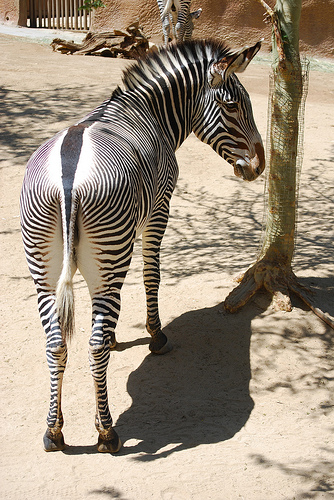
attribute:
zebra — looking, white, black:
[13, 26, 278, 455]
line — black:
[55, 118, 82, 241]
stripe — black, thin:
[60, 87, 113, 266]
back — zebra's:
[31, 98, 155, 193]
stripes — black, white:
[203, 82, 258, 150]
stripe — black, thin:
[61, 110, 95, 248]